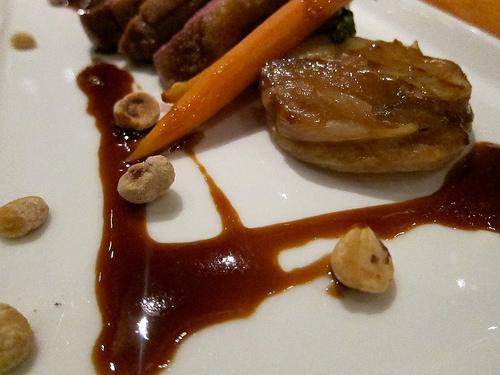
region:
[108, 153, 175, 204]
Coated peanut on a plate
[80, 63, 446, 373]
Sauce on a plate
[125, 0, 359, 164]
Carrot on a plate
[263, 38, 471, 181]
Pastry on a plate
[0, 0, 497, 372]
White plate on a table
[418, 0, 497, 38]
Wooden table under a plate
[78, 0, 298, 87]
Meat on a plate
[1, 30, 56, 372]
Three peanuts scattered on a plate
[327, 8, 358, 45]
Green vegetable between a carrot and pastry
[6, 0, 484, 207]
Food arranged on a plate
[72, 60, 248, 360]
Brown sauce drizzled on plate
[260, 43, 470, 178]
Stack of food sitting on plate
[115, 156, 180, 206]
Nut that has been sprinkled on plate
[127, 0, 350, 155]
Orange carrot on the plate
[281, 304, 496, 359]
Portion of the white plate food is sitting on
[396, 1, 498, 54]
Edge of the white plate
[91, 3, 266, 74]
Dark food on the back of the plate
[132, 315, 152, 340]
Reflection of the light in sauce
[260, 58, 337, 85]
Glistening light on the food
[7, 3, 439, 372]
Variety of foods sitting on the white plate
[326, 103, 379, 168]
edge of a food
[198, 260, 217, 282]
part of a honey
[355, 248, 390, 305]
part of a food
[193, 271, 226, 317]
part of a honey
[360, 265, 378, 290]
edge of a food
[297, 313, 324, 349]
part of a plate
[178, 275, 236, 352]
part of a honey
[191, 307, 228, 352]
aprt f a honet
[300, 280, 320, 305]
part of a tray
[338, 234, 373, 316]
part of a line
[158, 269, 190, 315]
part of a soup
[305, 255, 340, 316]
part of a honey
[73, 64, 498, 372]
Brown sauce dripped around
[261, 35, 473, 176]
Two flat brown things by the sauce stacked up.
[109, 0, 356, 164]
A long orange carrot.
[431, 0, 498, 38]
A tiny piece of a brown table.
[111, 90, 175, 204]
Two tan nuts with a carrot between them.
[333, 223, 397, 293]
The largest tan nut.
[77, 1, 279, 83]
Three pieces of dark brown foot to the left of the carrots.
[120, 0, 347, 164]
Long skinny orange carrot.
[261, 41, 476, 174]
Two stacked up round brown pieces of food.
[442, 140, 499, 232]
Large round brown spot of sauce by the stacked up food.